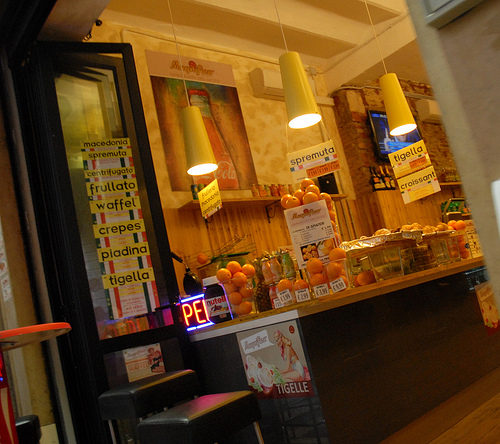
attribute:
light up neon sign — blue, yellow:
[177, 293, 218, 332]